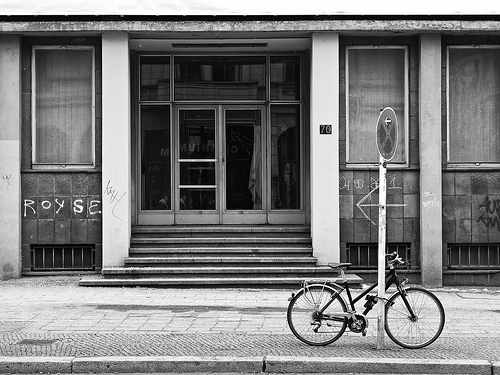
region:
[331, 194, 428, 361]
a bike is parked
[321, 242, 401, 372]
a bike is parked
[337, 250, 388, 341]
a bike is parked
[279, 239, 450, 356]
black commuter bicycle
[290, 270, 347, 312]
silver rear cargo bike rack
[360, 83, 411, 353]
sign post with round sign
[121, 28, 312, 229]
glass building office doors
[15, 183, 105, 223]
white spray paint grafetti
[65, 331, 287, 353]
stone brick sidewalk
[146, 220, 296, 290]
cement office stairs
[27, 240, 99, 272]
window with bars on it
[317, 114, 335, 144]
address numerals on a building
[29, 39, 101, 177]
office window with blinds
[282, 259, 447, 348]
a parked bicycle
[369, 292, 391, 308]
a bicycle chain lock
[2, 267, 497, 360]
a brick paved sidewalk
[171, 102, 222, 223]
an entry doorway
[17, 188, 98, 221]
white painted graffiti tag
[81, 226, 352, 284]
a set of entry steps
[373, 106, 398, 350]
a traffic information sign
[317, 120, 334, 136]
sign marked building number 70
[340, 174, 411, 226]
white spray painted graffiti markings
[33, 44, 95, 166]
a tall glass window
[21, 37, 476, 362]
A black and white photograph.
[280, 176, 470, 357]
Bicycle attached to a pole.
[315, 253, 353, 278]
Seat on a bicycle.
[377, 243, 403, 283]
Handlebars on a bicycle.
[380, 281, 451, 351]
Front wheel on a bicycle.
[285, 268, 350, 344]
Back wheel on a bicycle.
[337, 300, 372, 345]
Pedals on a bicycle.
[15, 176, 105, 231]
Graffiti on left side of building.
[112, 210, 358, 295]
Steps going up to door of building.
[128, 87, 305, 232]
Glass doors on front of building.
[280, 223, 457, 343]
A bike is locked to a pole.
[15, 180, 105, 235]
Grafiti on the wall.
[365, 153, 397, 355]
A sign pole on the side walk.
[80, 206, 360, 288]
The stairs in front of the building.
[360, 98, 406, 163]
A sign on the pole.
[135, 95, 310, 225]
The front door on the building.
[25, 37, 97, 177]
The window on the buidling.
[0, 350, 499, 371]
The curb on the sidewalk.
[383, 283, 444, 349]
The front wheel on the bicycle.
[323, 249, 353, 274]
The seat on the bicycle.